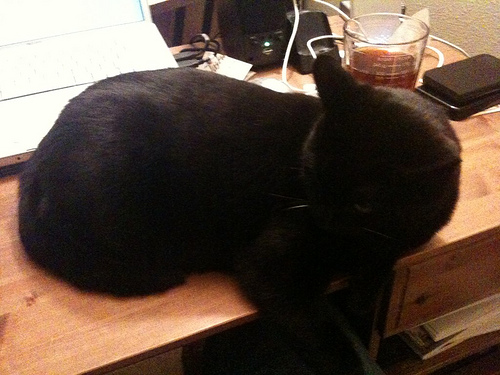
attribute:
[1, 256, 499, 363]
table — side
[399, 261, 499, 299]
drawer — edge, closed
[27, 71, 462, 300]
cat — black, sleeping, sitting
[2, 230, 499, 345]
desk — wooden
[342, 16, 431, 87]
glass — dark, mug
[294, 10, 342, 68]
wire — white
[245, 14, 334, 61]
chargers — black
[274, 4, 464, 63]
cords — white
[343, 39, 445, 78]
cup — measuring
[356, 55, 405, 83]
liquid — brown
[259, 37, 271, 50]
light — green